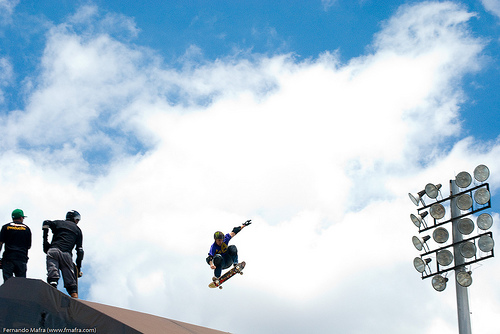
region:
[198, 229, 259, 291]
A person with skateboard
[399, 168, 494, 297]
Many lights with metal pole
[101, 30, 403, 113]
Blue color sky with clouds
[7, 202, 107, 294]
Two pepole standing with skateboard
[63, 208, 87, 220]
A person wearing helmet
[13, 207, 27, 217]
A person wearing green color hat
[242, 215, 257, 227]
A person wearing black color glove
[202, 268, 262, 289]
Skateboard with wheels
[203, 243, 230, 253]
A person wearing blue color t-shirt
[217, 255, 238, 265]
A person wearing blue color jean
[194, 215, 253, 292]
A skateboarder in the air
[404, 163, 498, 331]
A light stand with multiple bulbs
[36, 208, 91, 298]
A man leans on a skateboard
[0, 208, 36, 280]
A man looks on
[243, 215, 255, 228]
A black glove on the hand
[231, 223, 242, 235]
A black elbow pad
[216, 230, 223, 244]
Man wears black helmet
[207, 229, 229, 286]
Man holds his leg in air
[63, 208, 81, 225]
Man wears black helmet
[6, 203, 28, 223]
A blue baseball cap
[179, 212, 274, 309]
the boy is doing skateboard trick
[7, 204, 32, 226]
the cap is green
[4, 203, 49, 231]
the cap is green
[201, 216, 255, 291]
The skateboarder is in the air.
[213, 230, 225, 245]
The skateboarder wears a helmet.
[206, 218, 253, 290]
Th skateboarder holds his left arm out.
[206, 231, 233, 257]
The skateboarder has a blue shirt.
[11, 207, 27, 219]
The hat is green.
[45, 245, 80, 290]
The pants are gray.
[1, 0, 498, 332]
A large white cloud is in the sky.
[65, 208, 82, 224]
The skateboarder is wearing a helmet.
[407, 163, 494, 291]
The lights are turned off.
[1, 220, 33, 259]
The shirt is black.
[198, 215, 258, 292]
Guy is skateboarding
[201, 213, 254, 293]
Skateboarder wearing blue shirt.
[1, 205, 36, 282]
Man wearing green hat.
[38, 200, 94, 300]
Skateboarder wearing grey pants.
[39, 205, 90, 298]
Skateboarder wearing helmet.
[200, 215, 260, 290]
Skateboarder doing a trick.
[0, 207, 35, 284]
Man wearing black shirt with yellow writing.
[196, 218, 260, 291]
Skateboarder wearing knee pads.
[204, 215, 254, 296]
Skateboarder wearing elbow pads.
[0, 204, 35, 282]
Man standing next to skateboarder.